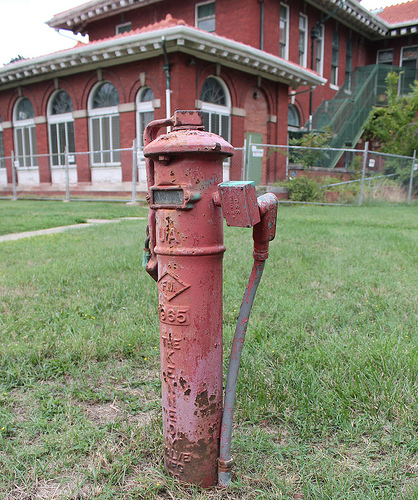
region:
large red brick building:
[24, 3, 400, 191]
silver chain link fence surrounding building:
[14, 149, 141, 195]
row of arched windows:
[12, 76, 152, 124]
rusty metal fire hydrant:
[137, 99, 300, 482]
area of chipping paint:
[182, 375, 220, 434]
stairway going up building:
[310, 60, 392, 160]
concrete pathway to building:
[11, 194, 142, 255]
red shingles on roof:
[95, 8, 188, 46]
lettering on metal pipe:
[151, 214, 216, 470]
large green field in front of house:
[10, 202, 393, 480]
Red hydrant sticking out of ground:
[103, 75, 277, 475]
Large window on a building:
[133, 76, 156, 193]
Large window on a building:
[84, 77, 121, 183]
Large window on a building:
[36, 82, 81, 199]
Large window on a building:
[6, 93, 45, 190]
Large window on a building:
[197, 67, 241, 161]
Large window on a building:
[282, 100, 302, 132]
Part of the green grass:
[54, 233, 114, 302]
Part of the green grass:
[329, 440, 395, 497]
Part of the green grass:
[291, 346, 391, 418]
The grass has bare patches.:
[3, 391, 130, 497]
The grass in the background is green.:
[11, 255, 76, 295]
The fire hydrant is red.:
[137, 113, 276, 499]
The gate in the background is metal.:
[243, 132, 376, 207]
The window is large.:
[83, 79, 130, 188]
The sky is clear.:
[3, 5, 42, 43]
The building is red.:
[216, 2, 260, 38]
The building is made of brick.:
[215, 2, 260, 42]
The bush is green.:
[280, 175, 319, 201]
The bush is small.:
[281, 169, 323, 204]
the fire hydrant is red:
[58, 138, 416, 329]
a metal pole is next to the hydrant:
[187, 398, 289, 491]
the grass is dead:
[40, 412, 146, 469]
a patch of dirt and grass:
[47, 370, 173, 493]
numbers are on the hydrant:
[143, 283, 253, 373]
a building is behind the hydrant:
[62, 70, 269, 246]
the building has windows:
[31, 139, 151, 216]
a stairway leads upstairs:
[286, 57, 414, 172]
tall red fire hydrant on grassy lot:
[0, 108, 411, 488]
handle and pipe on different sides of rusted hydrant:
[134, 105, 273, 482]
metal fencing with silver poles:
[0, 143, 414, 200]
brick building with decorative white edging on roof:
[0, 0, 410, 199]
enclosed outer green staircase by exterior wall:
[298, 57, 410, 183]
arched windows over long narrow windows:
[0, 66, 235, 192]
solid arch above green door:
[233, 84, 266, 179]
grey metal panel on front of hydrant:
[140, 178, 192, 208]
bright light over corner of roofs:
[0, 0, 86, 64]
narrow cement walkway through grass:
[1, 210, 143, 244]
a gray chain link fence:
[248, 141, 416, 209]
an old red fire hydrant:
[141, 102, 279, 494]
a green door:
[245, 130, 262, 183]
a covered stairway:
[301, 59, 412, 170]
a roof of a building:
[370, 0, 416, 22]